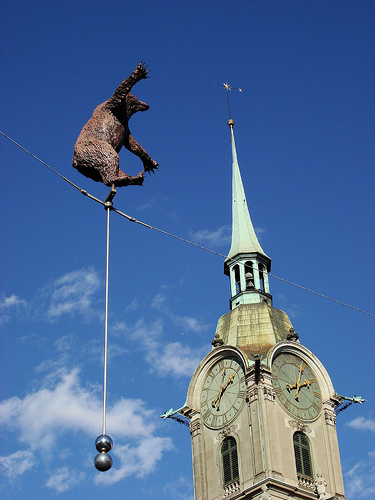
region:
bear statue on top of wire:
[71, 60, 159, 189]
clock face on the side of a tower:
[184, 345, 248, 429]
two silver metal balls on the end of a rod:
[93, 206, 112, 471]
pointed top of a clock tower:
[201, 79, 271, 309]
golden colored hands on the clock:
[284, 359, 317, 400]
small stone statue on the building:
[312, 471, 329, 498]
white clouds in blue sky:
[1, 1, 373, 498]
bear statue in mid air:
[72, 61, 161, 185]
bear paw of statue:
[134, 59, 150, 81]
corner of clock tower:
[170, 119, 359, 498]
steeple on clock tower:
[222, 120, 270, 273]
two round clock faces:
[199, 350, 322, 430]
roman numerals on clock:
[197, 357, 244, 427]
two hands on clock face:
[210, 368, 234, 410]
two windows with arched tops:
[221, 429, 313, 490]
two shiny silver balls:
[95, 434, 111, 471]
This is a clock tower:
[182, 67, 345, 481]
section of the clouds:
[107, 356, 179, 466]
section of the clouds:
[304, 302, 373, 364]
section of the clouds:
[1, 1, 97, 113]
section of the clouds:
[243, 26, 373, 171]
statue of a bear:
[64, 59, 171, 196]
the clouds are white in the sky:
[14, 386, 63, 430]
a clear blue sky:
[302, 208, 345, 258]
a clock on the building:
[193, 361, 253, 426]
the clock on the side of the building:
[271, 353, 326, 419]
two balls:
[92, 437, 115, 468]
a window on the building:
[219, 438, 241, 485]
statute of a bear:
[72, 64, 158, 188]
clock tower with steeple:
[156, 82, 364, 498]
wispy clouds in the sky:
[6, 171, 374, 498]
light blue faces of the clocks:
[197, 356, 319, 422]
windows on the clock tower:
[218, 421, 314, 484]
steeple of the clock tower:
[207, 79, 271, 253]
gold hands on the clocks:
[201, 362, 314, 409]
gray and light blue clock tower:
[167, 124, 354, 498]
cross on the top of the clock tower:
[212, 73, 246, 117]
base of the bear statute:
[99, 183, 116, 206]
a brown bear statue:
[74, 59, 158, 188]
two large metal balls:
[95, 435, 113, 470]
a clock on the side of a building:
[196, 360, 248, 430]